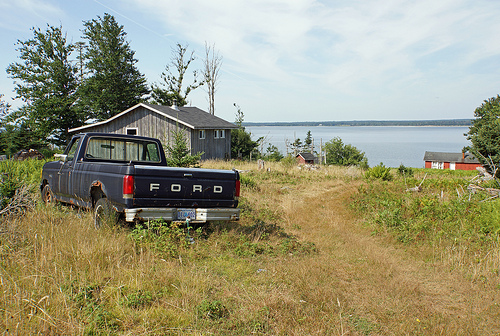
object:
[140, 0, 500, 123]
clouds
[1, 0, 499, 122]
blue sky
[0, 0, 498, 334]
photo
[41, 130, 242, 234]
truck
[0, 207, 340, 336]
grass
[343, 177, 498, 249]
grass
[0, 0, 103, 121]
clouds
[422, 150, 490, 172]
red building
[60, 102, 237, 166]
house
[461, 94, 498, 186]
tree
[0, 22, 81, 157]
tree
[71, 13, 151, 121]
tree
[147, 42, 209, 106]
tree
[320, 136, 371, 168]
tree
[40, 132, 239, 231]
blue_truck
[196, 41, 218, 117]
trees